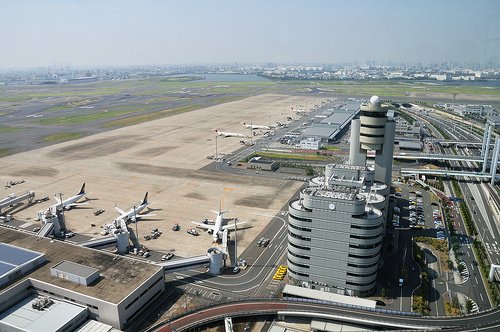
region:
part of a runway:
[162, 136, 195, 169]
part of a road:
[311, 292, 345, 329]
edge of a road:
[250, 304, 280, 321]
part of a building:
[347, 114, 376, 151]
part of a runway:
[158, 152, 193, 192]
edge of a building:
[271, 214, 293, 255]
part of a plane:
[208, 203, 226, 218]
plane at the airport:
[98, 193, 159, 243]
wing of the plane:
[140, 206, 160, 231]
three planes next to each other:
[51, 160, 249, 245]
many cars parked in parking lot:
[396, 193, 440, 238]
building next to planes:
[263, 193, 379, 288]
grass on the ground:
[141, 78, 204, 98]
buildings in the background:
[341, 56, 404, 87]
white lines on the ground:
[249, 245, 277, 276]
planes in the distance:
[214, 112, 281, 142]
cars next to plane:
[141, 223, 171, 243]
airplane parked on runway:
[176, 203, 249, 236]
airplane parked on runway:
[93, 194, 162, 225]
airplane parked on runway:
[40, 185, 93, 213]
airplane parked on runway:
[213, 123, 242, 135]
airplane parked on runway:
[240, 115, 272, 131]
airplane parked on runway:
[288, 105, 308, 114]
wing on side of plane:
[227, 222, 246, 231]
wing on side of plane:
[189, 217, 206, 228]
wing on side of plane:
[135, 212, 155, 217]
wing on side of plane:
[109, 204, 120, 216]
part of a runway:
[167, 162, 202, 197]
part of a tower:
[317, 212, 366, 274]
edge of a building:
[344, 210, 384, 277]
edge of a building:
[280, 210, 310, 255]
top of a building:
[312, 182, 373, 214]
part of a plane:
[211, 195, 223, 216]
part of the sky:
[261, 39, 274, 49]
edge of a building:
[104, 283, 144, 314]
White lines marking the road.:
[238, 253, 284, 300]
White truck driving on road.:
[390, 269, 413, 292]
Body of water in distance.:
[191, 67, 291, 93]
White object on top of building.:
[363, 92, 383, 100]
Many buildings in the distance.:
[232, 33, 469, 99]